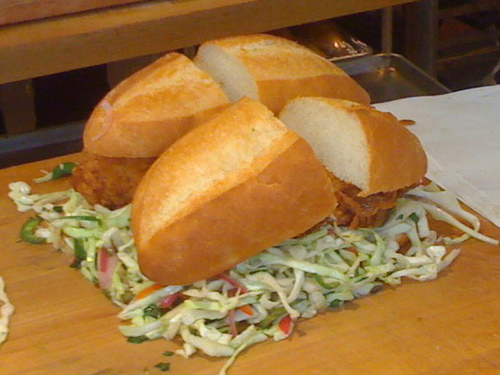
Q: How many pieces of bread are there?
A: 4.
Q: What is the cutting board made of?
A: Wood.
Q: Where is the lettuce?
A: Under the bread.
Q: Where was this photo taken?
A: In the kitchen.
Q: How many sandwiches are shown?
A: Two.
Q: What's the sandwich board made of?
A: Wood.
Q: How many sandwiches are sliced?
A: Two.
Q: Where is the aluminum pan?
A: Below the table.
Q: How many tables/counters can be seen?
A: Two.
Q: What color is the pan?
A: Silver.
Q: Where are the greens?
A: Falling onto board.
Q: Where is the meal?
A: On the table.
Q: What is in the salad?
A: Shredded cabbage.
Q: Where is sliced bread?
A: On top of salad.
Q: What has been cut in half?
A: Bread.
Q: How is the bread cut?
A: In half.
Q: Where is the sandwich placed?
A: On a table.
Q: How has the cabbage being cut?
A: In small pieces.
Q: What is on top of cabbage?
A: Bread.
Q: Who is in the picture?
A: No one.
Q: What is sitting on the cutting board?
A: Sandwiches.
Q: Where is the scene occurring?
A: In a kitchen.